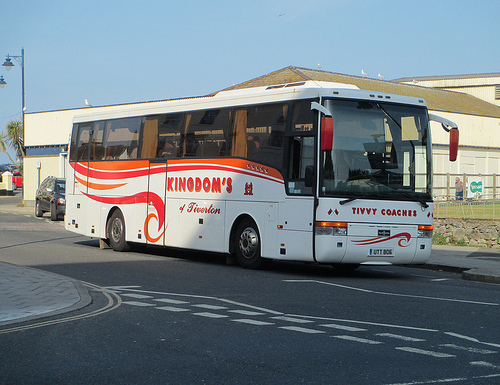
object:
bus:
[63, 79, 459, 270]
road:
[0, 191, 500, 385]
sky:
[0, 0, 500, 114]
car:
[34, 176, 66, 220]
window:
[75, 122, 93, 162]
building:
[23, 65, 499, 202]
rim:
[238, 227, 259, 260]